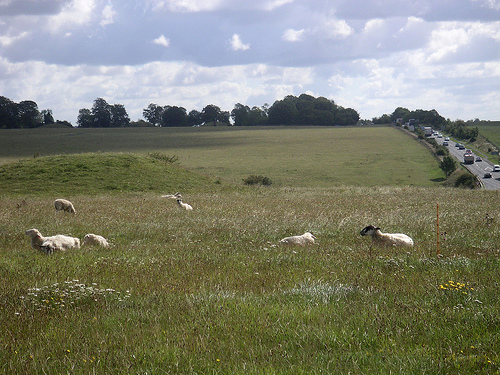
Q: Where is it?
A: This is at the field.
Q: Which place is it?
A: It is a field.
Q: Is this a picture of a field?
A: Yes, it is showing a field.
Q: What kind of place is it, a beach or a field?
A: It is a field.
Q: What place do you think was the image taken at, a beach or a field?
A: It was taken at a field.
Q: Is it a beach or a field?
A: It is a field.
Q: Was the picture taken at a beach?
A: No, the picture was taken in a field.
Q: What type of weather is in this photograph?
A: It is cloudy.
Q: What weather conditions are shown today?
A: It is cloudy.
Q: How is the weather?
A: It is cloudy.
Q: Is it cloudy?
A: Yes, it is cloudy.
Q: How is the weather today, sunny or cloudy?
A: It is cloudy.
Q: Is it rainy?
A: No, it is cloudy.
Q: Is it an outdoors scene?
A: Yes, it is outdoors.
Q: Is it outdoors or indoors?
A: It is outdoors.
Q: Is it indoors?
A: No, it is outdoors.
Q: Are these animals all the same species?
A: Yes, all the animals are sheep.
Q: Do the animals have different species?
A: No, all the animals are sheep.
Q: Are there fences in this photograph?
A: No, there are no fences.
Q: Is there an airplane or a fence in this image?
A: No, there are no fences or airplanes.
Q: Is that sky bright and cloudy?
A: Yes, the sky is bright and cloudy.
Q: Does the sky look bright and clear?
A: No, the sky is bright but cloudy.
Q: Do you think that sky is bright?
A: Yes, the sky is bright.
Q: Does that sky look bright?
A: Yes, the sky is bright.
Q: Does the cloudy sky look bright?
A: Yes, the sky is bright.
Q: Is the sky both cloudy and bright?
A: Yes, the sky is cloudy and bright.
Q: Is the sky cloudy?
A: Yes, the sky is cloudy.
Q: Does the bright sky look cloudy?
A: Yes, the sky is cloudy.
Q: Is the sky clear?
A: No, the sky is cloudy.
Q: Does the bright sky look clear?
A: No, the sky is cloudy.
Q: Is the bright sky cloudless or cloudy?
A: The sky is cloudy.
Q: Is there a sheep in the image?
A: Yes, there is a sheep.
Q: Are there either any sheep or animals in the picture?
A: Yes, there is a sheep.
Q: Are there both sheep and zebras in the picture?
A: No, there is a sheep but no zebras.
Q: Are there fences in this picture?
A: No, there are no fences.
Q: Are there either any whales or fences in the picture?
A: No, there are no fences or whales.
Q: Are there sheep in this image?
A: Yes, there is a sheep.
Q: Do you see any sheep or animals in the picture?
A: Yes, there is a sheep.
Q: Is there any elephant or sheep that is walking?
A: Yes, the sheep is walking.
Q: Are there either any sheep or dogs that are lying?
A: Yes, the sheep is lying.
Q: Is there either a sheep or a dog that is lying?
A: Yes, the sheep is lying.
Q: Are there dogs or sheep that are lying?
A: Yes, the sheep is lying.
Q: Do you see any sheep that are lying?
A: Yes, there is a sheep that is lying.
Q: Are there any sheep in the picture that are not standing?
A: Yes, there is a sheep that is lying.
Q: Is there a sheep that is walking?
A: Yes, there is a sheep that is walking.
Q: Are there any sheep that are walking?
A: Yes, there is a sheep that is walking.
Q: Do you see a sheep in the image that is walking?
A: Yes, there is a sheep that is walking.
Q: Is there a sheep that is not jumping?
A: Yes, there is a sheep that is walking.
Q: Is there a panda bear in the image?
A: No, there are no pandas.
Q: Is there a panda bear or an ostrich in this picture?
A: No, there are no pandas or ostriches.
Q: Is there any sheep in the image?
A: Yes, there is a sheep.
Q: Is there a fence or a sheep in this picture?
A: Yes, there is a sheep.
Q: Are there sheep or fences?
A: Yes, there is a sheep.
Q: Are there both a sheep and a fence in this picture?
A: No, there is a sheep but no fences.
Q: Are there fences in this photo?
A: No, there are no fences.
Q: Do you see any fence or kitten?
A: No, there are no fences or kittens.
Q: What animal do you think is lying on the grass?
A: The sheep is lying on the grass.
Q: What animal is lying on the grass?
A: The sheep is lying on the grass.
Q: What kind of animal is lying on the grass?
A: The animal is a sheep.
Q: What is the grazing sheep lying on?
A: The sheep is lying on the grass.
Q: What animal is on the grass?
A: The animal is a sheep.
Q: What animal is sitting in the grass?
A: The sheep is sitting in the grass.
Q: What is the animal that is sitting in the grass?
A: The animal is a sheep.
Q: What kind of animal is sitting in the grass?
A: The animal is a sheep.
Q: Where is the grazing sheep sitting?
A: The sheep is sitting in the grass.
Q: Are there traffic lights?
A: No, there are no traffic lights.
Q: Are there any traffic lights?
A: No, there are no traffic lights.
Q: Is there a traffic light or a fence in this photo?
A: No, there are no traffic lights or fences.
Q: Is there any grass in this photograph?
A: Yes, there is grass.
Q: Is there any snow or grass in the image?
A: Yes, there is grass.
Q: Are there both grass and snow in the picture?
A: No, there is grass but no snow.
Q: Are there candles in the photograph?
A: No, there are no candles.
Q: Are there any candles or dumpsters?
A: No, there are no candles or dumpsters.